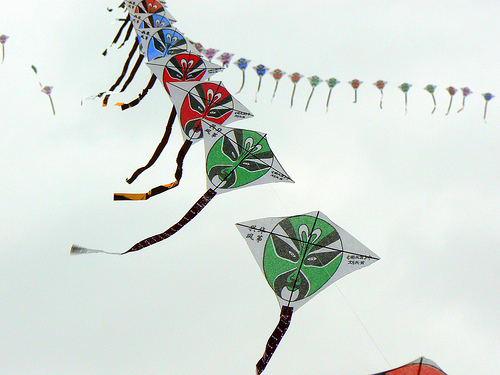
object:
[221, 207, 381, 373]
kite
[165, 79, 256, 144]
kite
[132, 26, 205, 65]
kite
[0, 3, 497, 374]
sky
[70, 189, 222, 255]
tail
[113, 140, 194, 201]
tail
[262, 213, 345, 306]
design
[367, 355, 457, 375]
kite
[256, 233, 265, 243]
word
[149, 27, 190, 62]
mask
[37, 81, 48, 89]
string